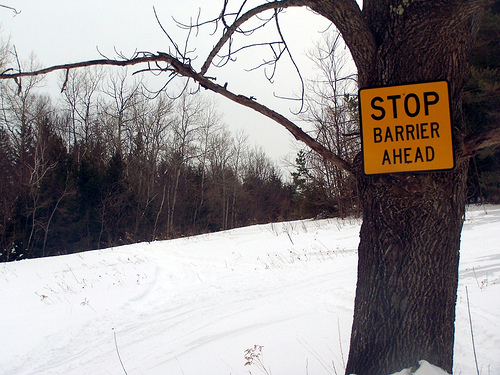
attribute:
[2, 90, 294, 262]
trees — leafless